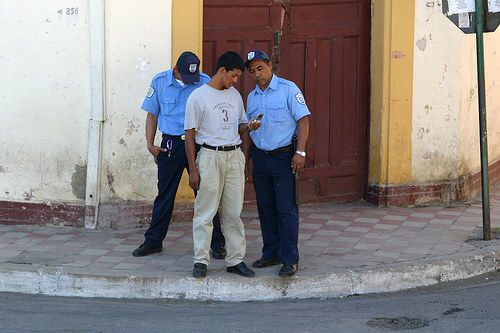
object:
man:
[131, 51, 226, 260]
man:
[240, 50, 310, 277]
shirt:
[140, 68, 215, 135]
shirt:
[246, 74, 311, 149]